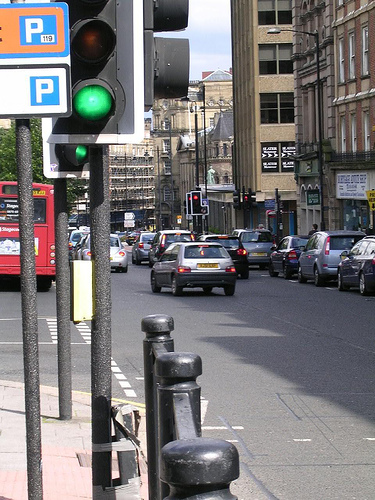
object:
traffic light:
[71, 81, 117, 126]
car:
[151, 240, 237, 295]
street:
[0, 250, 373, 498]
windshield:
[182, 243, 229, 261]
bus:
[0, 181, 55, 293]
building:
[232, 0, 296, 232]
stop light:
[191, 193, 199, 203]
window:
[259, 90, 295, 126]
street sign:
[0, 3, 71, 118]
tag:
[195, 262, 222, 270]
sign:
[260, 143, 296, 175]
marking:
[199, 425, 247, 430]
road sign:
[363, 189, 375, 212]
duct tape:
[91, 440, 139, 453]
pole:
[92, 146, 113, 499]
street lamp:
[265, 27, 283, 35]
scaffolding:
[110, 152, 155, 216]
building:
[108, 118, 154, 232]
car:
[297, 230, 366, 288]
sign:
[334, 172, 369, 199]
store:
[336, 198, 374, 232]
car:
[76, 232, 128, 272]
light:
[178, 267, 191, 275]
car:
[198, 234, 249, 281]